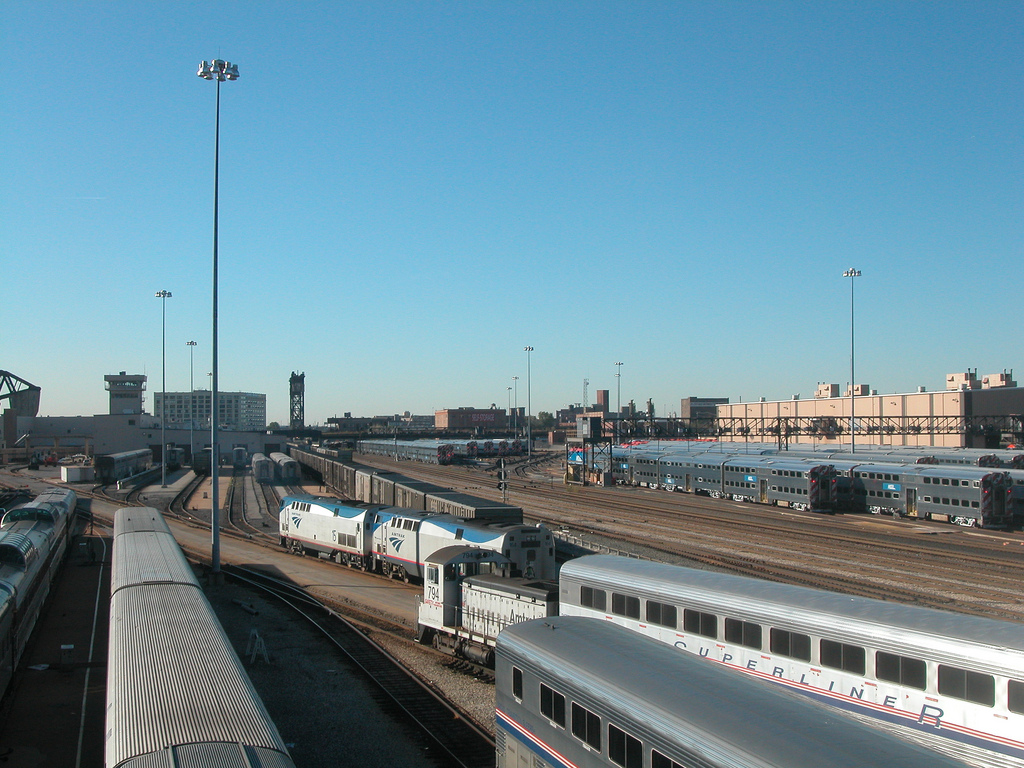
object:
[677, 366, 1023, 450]
building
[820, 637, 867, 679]
window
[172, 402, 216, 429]
window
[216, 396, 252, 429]
window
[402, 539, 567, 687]
engine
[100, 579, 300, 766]
train car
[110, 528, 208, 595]
train car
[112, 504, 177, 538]
train car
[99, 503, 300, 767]
train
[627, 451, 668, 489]
train car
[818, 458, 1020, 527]
train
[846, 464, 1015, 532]
train car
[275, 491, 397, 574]
train engine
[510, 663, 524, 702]
window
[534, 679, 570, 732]
window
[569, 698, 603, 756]
window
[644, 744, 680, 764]
window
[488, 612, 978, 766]
train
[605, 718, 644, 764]
window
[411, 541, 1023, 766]
train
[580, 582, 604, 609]
window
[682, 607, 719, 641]
window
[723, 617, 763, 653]
window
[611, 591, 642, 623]
window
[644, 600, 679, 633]
window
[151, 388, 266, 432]
building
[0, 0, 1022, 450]
distance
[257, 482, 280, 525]
tracks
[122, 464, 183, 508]
set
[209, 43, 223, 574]
light pole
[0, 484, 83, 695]
train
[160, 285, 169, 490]
light pole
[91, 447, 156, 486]
train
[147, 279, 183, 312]
light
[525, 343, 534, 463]
light poles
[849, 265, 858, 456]
light pole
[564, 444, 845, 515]
train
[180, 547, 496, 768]
track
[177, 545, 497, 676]
track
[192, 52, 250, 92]
light fixture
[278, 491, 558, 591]
train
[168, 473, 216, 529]
track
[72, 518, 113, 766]
track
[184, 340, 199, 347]
light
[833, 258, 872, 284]
light fixture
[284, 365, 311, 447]
tower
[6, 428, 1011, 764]
train depot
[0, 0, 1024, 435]
sky